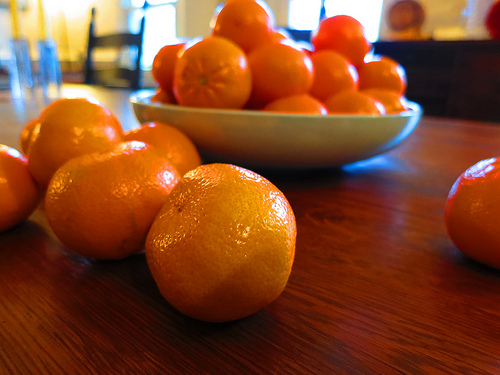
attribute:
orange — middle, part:
[139, 161, 299, 326]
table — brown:
[314, 213, 421, 345]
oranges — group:
[169, 14, 414, 131]